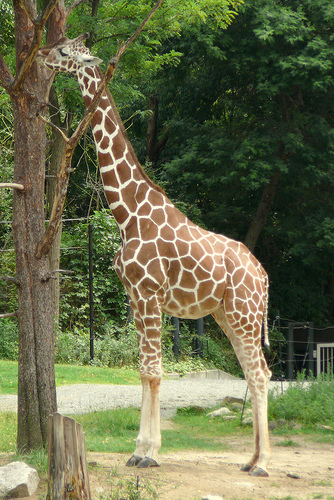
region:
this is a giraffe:
[41, 12, 286, 485]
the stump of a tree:
[35, 404, 92, 498]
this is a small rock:
[1, 451, 41, 498]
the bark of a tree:
[9, 164, 67, 448]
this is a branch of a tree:
[212, 101, 290, 187]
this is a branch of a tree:
[229, 40, 327, 101]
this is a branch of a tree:
[88, 1, 240, 50]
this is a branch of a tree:
[155, 118, 262, 214]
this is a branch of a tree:
[279, 183, 333, 264]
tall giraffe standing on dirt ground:
[26, 27, 280, 484]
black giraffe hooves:
[116, 446, 170, 473]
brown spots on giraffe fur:
[159, 251, 195, 287]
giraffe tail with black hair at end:
[256, 266, 279, 360]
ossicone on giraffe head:
[75, 28, 97, 44]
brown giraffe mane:
[94, 67, 177, 205]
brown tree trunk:
[31, 409, 100, 498]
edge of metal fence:
[310, 337, 330, 383]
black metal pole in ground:
[80, 220, 106, 366]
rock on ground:
[282, 468, 313, 484]